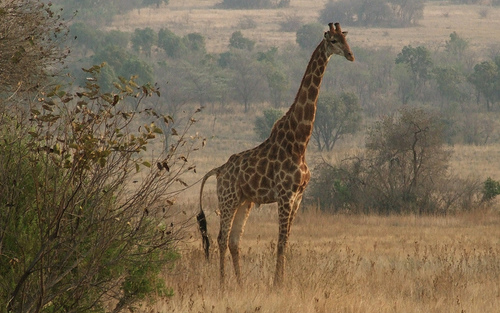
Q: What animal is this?
A: Giraffe.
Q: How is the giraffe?
A: Standing.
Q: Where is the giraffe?
A: In the field.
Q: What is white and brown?
A: Giraffe's coloring.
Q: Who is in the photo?
A: No humans.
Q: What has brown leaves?
A: The bush.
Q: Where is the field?
A: In Africa.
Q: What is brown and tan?
A: Giraffe.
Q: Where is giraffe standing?
A: Dry foliage.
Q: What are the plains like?
A: Very dry.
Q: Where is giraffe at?
A: Open field.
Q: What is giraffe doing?
A: Standing still.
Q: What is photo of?
A: Giraffe in foliage.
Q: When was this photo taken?
A: Daytime.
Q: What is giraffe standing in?
A: Field.